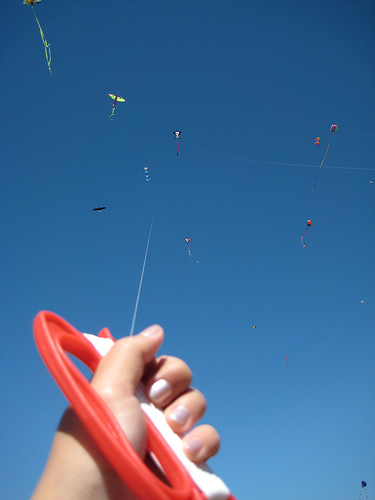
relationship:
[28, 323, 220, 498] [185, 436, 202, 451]
boy has polish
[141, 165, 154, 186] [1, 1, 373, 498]
blue kite in sky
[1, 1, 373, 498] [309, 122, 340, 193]
sky filled with kite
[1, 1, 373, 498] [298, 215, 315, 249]
sky filled with kite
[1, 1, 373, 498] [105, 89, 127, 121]
sky filled with kite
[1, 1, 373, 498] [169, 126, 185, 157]
sky filled with kite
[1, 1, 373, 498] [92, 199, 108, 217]
sky filled with kite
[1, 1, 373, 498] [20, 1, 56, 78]
sky filled with kite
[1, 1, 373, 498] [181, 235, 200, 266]
sky filled with kite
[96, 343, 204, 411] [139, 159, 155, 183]
hand holding onto kite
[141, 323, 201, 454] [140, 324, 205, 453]
polish on nails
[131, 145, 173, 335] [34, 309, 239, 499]
string around handle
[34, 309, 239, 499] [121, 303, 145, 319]
handle wrapped with string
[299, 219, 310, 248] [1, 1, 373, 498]
kite in sky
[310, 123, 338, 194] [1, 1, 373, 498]
kite in sky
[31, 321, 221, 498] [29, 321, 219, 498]
hand belonging to person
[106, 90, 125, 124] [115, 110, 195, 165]
kite attached to thread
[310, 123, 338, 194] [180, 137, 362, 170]
kite attached to thread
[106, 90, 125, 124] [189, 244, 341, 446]
kite attached to thread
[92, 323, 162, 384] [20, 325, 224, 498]
thumb belonging to boy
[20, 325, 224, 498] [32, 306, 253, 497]
boy holding holder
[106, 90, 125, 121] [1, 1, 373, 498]
kite flying in sky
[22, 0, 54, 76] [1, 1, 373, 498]
kite flying in sky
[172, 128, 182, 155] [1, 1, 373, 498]
kite flying in sky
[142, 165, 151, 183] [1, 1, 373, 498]
blue kite flying in sky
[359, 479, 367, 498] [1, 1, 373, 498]
kite flying in sky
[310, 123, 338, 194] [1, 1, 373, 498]
kite flying in sky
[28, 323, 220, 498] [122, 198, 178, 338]
boy holding string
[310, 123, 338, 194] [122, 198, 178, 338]
kite attached to string